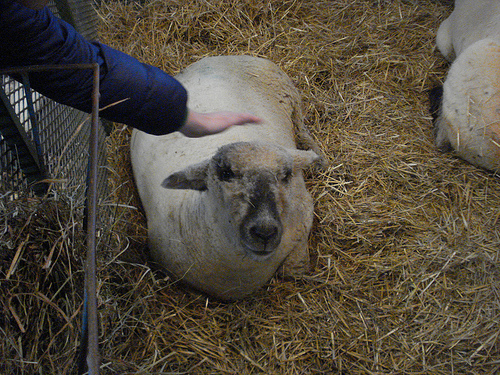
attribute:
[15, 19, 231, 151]
coat — blue 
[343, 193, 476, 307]
straw — golden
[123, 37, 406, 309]
sheep — white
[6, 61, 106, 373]
fence — metal 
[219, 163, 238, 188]
eye — black 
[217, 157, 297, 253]
face — black 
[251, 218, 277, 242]
nose — black 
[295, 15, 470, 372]
hay — yellow , brown 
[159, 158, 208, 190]
ear — fuzzy 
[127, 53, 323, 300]
sheep — white, petted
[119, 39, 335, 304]
sheep — nearby, white